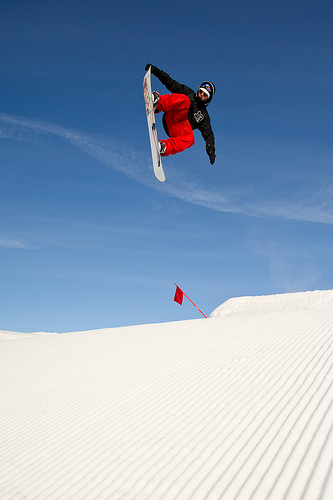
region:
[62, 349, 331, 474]
snow is white and combed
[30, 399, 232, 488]
snow is white and combed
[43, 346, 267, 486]
snow is white and combed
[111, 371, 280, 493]
snow is white and combed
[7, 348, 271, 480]
snow is white and combed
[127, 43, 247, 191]
a person snowboarding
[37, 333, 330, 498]
white snow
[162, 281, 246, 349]
a ski flag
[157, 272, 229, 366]
a red ski flag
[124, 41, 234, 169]
a person wearing red ski pants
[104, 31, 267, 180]
a person wearing a black jacket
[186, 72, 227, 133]
a person wearing a hood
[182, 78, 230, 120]
a person wearing a hat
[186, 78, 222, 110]
a person wearing glasses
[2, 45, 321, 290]
blue sky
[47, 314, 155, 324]
sky is clear and blue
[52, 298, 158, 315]
sky is clear and blue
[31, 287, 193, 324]
sky is clear and blue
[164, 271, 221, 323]
red flag in snow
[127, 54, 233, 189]
snowboarder floating through the air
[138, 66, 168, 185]
white snowboard with a design on the bottom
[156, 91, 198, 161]
red snow pants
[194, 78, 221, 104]
hooded head with sunglasses on face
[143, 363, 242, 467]
snow with little grooves in the surface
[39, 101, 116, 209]
blue sky and a wisp of couds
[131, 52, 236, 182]
snowboarder performing a trick one hand on end of board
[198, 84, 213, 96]
white billed hat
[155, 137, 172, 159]
boot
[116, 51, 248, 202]
man on snowboard mid air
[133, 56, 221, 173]
snowboarder doing trick in air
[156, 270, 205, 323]
red flag in snow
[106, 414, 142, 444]
tracks in white snow on hill side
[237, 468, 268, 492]
tracks in white snow on hill side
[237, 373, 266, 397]
tracks in white snow on hill side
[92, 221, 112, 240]
white clouds in blue sky